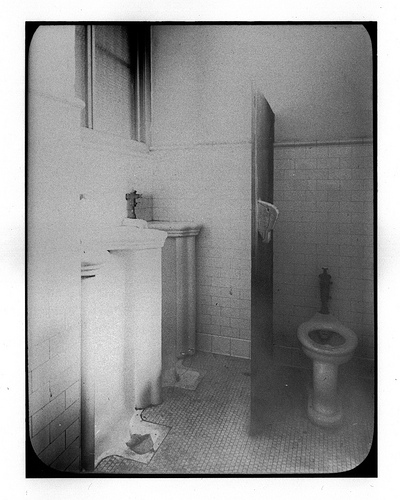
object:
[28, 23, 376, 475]
restroom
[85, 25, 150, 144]
blinds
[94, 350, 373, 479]
bathroom floor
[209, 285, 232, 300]
tile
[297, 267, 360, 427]
toilet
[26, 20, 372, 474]
wall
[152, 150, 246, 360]
wall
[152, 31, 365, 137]
wall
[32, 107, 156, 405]
wall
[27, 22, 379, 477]
border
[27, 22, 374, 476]
image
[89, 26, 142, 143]
window pane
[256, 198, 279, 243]
dispenser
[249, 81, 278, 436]
divider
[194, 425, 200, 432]
tiles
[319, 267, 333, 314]
pipe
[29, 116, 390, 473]
tiled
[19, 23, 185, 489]
wall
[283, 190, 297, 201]
brick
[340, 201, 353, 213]
brick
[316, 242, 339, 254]
brick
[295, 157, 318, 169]
brick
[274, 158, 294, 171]
brick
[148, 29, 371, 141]
white walls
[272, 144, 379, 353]
white walls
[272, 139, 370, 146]
edge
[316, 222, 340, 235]
tile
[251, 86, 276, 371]
wall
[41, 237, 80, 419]
wall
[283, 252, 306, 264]
tile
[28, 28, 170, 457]
wall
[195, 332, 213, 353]
baseboard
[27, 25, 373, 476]
magazine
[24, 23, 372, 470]
wall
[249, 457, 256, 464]
tiles